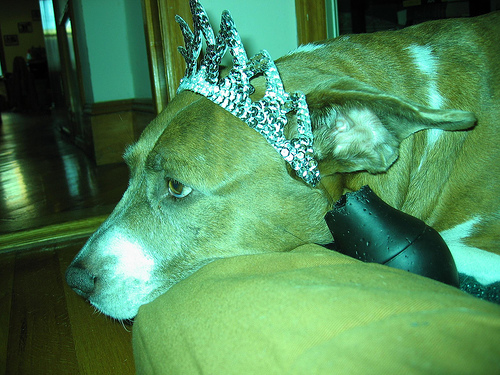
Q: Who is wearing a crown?
A: Dog.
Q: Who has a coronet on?
A: A dog.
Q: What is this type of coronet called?
A: A tiara.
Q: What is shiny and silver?
A: A tiara.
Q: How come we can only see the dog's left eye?
A: The dog is lying down, with his head pointed to the left.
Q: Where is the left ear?
A: Under, and right behind, the tiara.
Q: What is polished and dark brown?
A: The floor.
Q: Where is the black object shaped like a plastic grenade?
A: Below the dog's left ear, beside it.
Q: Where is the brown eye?
A: On the dog.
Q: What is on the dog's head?
A: A crown.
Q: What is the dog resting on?
A: A cushion.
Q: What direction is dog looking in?
A: Forward.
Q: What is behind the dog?
A: A doorway.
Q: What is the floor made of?
A: Wood.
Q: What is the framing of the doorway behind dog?
A: Wood.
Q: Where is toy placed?
A: Besides the dog.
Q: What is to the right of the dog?
A: Image of hall.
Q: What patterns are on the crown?
A: Silver beads.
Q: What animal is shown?
A: A dog.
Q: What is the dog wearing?
A: A crown.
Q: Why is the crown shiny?
A: It has jewels on it.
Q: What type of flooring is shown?
A: Hardwood.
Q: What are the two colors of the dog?
A: Tan and white.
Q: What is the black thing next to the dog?
A: A chew toy.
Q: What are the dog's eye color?
A: Brown.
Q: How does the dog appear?
A: Sad.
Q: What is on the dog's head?
A: Tiara.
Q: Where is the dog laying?
A: On sofa.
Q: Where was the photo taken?
A: In living room.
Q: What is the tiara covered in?
A: Rhinestones.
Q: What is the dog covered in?
A: Fur.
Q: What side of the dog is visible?
A: Left side.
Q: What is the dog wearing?
A: A crown.